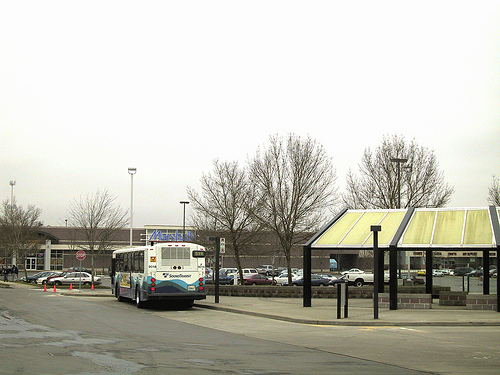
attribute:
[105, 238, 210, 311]
bus — long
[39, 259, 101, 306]
car — white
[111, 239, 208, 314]
bus — parked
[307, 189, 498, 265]
roof — glass like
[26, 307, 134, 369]
road — watery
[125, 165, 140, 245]
pole — white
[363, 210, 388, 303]
pole — black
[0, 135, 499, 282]
trees — dry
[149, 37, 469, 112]
sky — white 